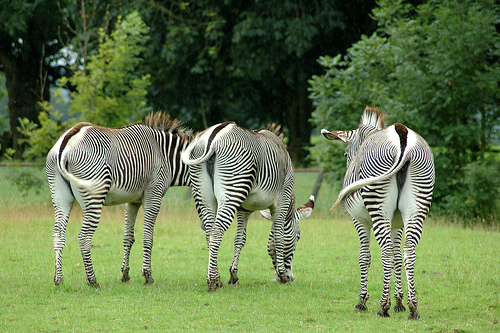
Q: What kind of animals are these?
A: Zebras.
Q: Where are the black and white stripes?
A: On the zebras.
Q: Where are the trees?
A: Behind the zebras.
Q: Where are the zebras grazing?
A: The field.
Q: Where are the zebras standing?
A: The field.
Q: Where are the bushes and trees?
A: Behind the pasture.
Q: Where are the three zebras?
A: In a pasture.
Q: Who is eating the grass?
A: Three zebras.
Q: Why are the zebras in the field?
A: To eat.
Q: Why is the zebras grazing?
A: Hunger.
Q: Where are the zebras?
A: In a field.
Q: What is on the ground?
A: Grass.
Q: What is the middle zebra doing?
A: Eating grass.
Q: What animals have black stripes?
A: The zebras.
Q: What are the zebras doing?
A: Grazing.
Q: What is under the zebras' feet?
A: Grass.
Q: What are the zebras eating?
A: Grass.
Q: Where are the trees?
A: Behind the zebras.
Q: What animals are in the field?
A: Zebras.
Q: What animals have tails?
A: The zebras.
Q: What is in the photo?
A: Animals.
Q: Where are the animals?
A: Outside on grass.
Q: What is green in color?
A: The grass.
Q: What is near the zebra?
A: Some trees.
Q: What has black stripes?
A: The animals.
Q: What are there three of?
A: Animals.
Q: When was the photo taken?
A: During the daytime.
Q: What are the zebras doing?
A: Eating grass.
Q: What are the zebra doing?
A: Eating.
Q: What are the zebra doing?
A: Eating grass.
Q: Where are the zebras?
A: On the grass.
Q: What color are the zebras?
A: White and black.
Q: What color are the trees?
A: Green.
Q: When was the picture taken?
A: Daytime.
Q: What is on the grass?
A: Zebras.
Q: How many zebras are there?
A: Three.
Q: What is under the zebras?
A: Grass.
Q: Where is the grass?
A: Under the zebras.